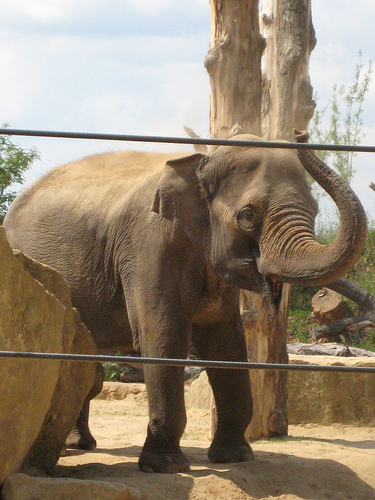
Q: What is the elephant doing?
A: Curling his truck.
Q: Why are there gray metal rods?
A: To keep the animal contained.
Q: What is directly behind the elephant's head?
A: Tree trunk.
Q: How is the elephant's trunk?
A: It is curled.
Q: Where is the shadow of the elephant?
A: On the ground in front of him.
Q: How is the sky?
A: Light blue with high thin clouds.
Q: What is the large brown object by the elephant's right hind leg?
A: Rock.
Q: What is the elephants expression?
A: Happy.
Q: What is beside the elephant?
A: Two barren tree trunks.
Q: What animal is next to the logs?
A: African elephant.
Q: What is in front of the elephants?
A: A metal bar.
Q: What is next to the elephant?
A: A large tan boulder.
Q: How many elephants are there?
A: One.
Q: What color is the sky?
A: Blue and white.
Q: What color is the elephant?
A: Gray.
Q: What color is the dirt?
A: Brown.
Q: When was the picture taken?
A: Daytime.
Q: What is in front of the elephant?
A: A fence.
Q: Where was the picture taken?
A: In a zoo.